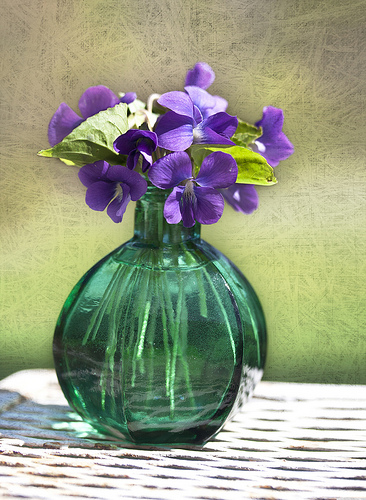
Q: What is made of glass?
A: The object.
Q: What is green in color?
A: The glass.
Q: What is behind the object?
A: The wall.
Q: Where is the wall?
A: Next to object.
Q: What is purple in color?
A: The flowers.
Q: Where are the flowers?
A: In the vase.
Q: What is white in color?
A: Table.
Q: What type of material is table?
A: Metal.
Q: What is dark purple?
A: Flower.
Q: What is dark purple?
A: Flowers.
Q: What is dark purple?
A: Flowers.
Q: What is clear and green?
A: Vase.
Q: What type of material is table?
A: Metal.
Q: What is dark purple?
A: Flowers.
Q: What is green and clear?
A: Vase.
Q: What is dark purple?
A: Flowers.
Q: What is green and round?
A: Vase.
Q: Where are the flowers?
A: A vase.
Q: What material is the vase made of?
A: Glass.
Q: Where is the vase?
A: On a white wicker table.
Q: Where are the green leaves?
A: In the bouquet.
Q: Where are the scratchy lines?
A: Behind the vase.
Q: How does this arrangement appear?
A: Pretty and royal purple.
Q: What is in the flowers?
A: Green leaves.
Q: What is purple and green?
A: Flowers.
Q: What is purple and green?
A: A vase.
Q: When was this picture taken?
A: Daytime.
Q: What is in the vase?
A: Flowers.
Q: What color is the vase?
A: Green.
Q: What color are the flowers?
A: Purple.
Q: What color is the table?
A: White.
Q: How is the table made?
A: Of wicker.